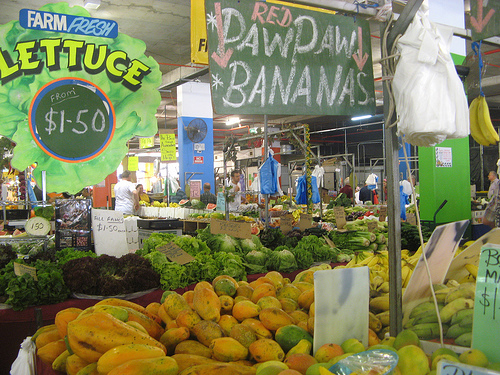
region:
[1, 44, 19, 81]
the letter l on sign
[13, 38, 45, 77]
letter e on sign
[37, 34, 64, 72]
letter t on sign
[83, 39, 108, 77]
letter u on sign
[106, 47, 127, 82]
letter c on sign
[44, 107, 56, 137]
dollar sign on sign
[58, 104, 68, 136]
number one on sign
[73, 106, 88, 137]
number five on sign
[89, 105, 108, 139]
number zero on sign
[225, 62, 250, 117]
letter b on sign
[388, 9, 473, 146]
A group of hanging plastic bags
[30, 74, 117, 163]
A hand written price display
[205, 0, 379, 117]
A chalk board sign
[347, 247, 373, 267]
A bunch of bananas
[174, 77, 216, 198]
A blue and white pillar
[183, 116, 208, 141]
A black fan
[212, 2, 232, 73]
A red arrow pointing down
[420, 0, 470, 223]
A green and white pillar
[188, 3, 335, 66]
A yellow banner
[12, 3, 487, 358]
A large farmers market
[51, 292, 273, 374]
A bin of yellow squash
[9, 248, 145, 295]
A bin of green and purple lettuce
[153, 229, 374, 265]
A long table of greens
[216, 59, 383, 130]
A sign saying Red Paw Paw Bananas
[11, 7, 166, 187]
A green sign saying Farm Fresh Lettuce $1.50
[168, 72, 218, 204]
A large blue and white sign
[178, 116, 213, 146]
A fan attached to a blue and white sign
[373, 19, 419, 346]
A metal pole with white plastic bags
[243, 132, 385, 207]
Blue and white bags hanging on poles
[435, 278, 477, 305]
banana on a stand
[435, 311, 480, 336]
banana on a stand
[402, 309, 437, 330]
banana on a stand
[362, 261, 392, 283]
banana on a stand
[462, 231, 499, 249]
banana on a stand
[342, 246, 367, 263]
banana on a stand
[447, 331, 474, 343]
banana on a stand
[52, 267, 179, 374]
this is a papaya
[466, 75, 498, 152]
this is a banana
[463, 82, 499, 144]
the banana is yellow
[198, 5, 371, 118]
white writing on sign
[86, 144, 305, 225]
people standing in market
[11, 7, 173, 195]
sign shaped like a lettuce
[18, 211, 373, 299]
different types of lettuce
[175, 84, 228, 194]
blue pillar in background